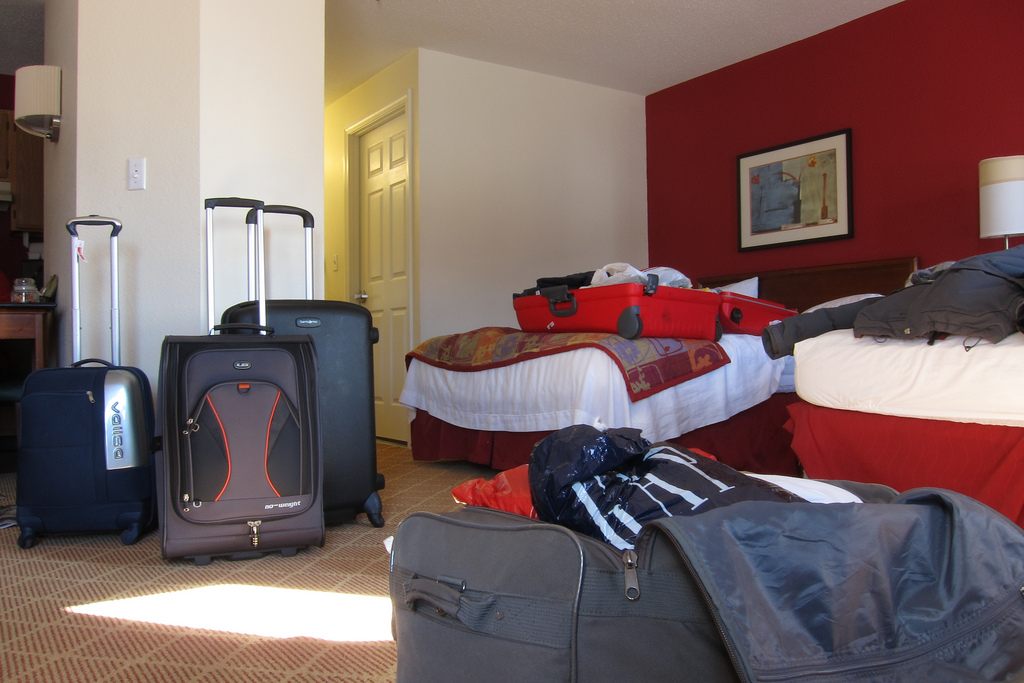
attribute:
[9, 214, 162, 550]
suitcase — standing, small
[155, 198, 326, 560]
suitcase — standing, gray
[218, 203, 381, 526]
suitcase — standing, black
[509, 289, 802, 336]
suitcase — red, open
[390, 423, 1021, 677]
bag — silver, black, opened, gray, plastic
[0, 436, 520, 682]
carpet — red, tan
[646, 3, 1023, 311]
wall — red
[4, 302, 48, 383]
desk — wooden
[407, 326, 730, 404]
blanket — patterned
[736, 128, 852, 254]
painting — framed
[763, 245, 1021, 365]
jacket — grey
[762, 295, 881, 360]
case — black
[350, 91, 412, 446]
door — white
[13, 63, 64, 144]
fixture — white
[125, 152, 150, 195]
switch — white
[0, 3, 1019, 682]
room — filled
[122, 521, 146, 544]
wheel — black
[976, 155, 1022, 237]
shade — brown, white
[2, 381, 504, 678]
floor — the